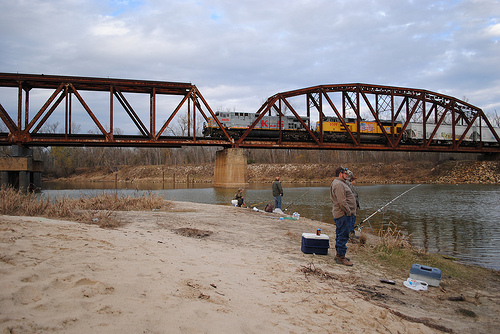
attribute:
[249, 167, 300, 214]
man — looking 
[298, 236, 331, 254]
ice chest — blue and white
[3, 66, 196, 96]
beam — rusty 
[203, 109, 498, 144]
train — going 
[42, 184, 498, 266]
water — calm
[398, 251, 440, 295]
tackle box — blue, white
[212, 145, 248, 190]
support — cement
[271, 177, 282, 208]
person — fishing 